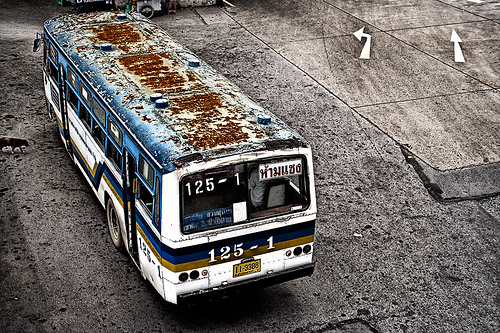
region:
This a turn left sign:
[349, 18, 377, 73]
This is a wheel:
[91, 196, 126, 241]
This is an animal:
[0, 128, 42, 163]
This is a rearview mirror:
[26, 35, 46, 55]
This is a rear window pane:
[178, 160, 313, 232]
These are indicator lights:
[176, 267, 214, 287]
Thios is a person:
[242, 172, 274, 214]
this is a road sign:
[436, 16, 477, 82]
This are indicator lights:
[278, 244, 322, 266]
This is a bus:
[36, 11, 318, 301]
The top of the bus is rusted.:
[77, 5, 257, 213]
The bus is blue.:
[30, 15, 302, 292]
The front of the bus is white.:
[165, 162, 347, 312]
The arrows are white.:
[343, 15, 487, 66]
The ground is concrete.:
[303, 96, 470, 213]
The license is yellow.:
[212, 259, 273, 287]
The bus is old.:
[32, 23, 349, 297]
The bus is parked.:
[5, 69, 349, 294]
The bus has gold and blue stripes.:
[37, 38, 212, 280]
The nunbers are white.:
[176, 158, 246, 200]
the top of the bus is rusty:
[65, 3, 310, 160]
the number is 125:
[173, 175, 220, 198]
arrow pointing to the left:
[309, 15, 401, 85]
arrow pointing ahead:
[416, 22, 486, 84]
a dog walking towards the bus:
[4, 117, 43, 186]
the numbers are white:
[188, 232, 290, 269]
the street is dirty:
[317, 15, 474, 148]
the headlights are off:
[170, 239, 315, 284]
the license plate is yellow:
[224, 252, 271, 280]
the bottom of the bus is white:
[117, 251, 322, 289]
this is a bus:
[73, 21, 289, 280]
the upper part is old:
[101, 26, 169, 96]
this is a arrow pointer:
[443, 21, 478, 71]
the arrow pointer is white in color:
[448, 23, 478, 64]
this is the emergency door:
[191, 174, 293, 204]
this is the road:
[349, 226, 475, 298]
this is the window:
[91, 124, 107, 141]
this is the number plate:
[231, 263, 264, 272]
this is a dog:
[3, 128, 24, 150]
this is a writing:
[188, 177, 229, 194]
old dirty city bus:
[34, 22, 314, 281]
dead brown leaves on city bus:
[49, 0, 267, 160]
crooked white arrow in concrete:
[339, 17, 381, 70]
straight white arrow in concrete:
[433, 14, 475, 75]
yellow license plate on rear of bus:
[228, 257, 273, 284]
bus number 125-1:
[183, 175, 244, 198]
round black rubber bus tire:
[101, 190, 134, 259]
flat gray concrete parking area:
[10, 17, 499, 318]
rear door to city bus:
[117, 148, 142, 264]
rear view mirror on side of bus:
[21, 24, 41, 57]